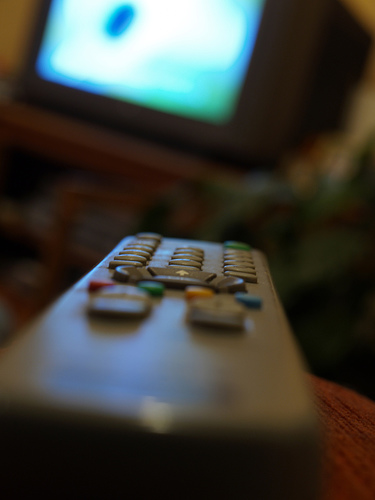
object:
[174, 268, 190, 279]
arrow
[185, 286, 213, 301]
button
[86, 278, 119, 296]
button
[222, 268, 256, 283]
grey button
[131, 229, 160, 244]
grey button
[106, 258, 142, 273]
grey button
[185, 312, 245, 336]
button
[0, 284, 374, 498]
table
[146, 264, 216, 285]
arrow key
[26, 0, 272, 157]
television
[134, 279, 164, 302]
button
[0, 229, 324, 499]
remote control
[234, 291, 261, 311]
blue button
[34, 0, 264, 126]
screen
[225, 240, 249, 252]
button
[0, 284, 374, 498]
surface